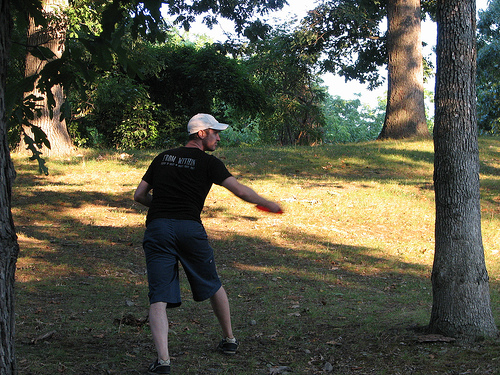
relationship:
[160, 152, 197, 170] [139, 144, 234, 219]
print on shirt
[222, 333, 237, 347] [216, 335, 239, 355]
socks in shoe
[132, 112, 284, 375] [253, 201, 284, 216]
man throwing frisbee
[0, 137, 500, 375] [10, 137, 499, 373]
leaves on ground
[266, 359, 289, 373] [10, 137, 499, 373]
leaves on ground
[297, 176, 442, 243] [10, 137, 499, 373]
sunny area on ground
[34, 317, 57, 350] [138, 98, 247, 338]
stick behind man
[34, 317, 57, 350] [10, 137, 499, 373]
stick on ground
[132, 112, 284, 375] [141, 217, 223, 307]
man wearing shorts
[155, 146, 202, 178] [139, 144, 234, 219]
writing on shirt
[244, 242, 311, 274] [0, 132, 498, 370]
shadow on grass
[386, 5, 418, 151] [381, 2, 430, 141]
shadow on tree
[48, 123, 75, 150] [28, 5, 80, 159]
sunlight on tree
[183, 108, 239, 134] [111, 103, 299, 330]
hat on man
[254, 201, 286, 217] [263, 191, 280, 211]
frisbee in hand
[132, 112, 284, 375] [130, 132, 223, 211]
man on shirt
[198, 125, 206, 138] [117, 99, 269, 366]
ear on man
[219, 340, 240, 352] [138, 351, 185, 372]
shoe on foot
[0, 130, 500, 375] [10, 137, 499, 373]
grass on ground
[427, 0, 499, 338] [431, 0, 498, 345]
bark on tree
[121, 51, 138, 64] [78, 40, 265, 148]
leaf on tree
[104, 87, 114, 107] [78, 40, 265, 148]
leaf on tree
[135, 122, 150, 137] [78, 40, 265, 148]
leaf on tree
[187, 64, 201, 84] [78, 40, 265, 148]
leaf on tree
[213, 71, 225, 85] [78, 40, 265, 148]
leaf on tree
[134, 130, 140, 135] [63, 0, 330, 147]
leaf on tree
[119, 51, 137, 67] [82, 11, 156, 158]
leaf on tree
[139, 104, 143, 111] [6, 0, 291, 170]
leaf on tree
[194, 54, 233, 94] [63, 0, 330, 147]
leaf on tree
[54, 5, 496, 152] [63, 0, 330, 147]
green leaf on tree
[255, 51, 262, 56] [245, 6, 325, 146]
leaf on tree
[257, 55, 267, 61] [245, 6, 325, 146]
leaf on tree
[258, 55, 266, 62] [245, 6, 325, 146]
leaf on tree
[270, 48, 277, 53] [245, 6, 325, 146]
leaf on tree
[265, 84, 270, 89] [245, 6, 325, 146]
leaf on tree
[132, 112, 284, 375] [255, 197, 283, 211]
man playing with frisbee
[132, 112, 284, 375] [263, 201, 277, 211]
man has hand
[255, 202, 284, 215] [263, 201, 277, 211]
frisbee in hand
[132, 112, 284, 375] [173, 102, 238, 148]
man wearing hat.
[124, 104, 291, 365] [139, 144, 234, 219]
man wearing shirt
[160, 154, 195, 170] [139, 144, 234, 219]
writing on shirt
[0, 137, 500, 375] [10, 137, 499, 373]
leaves scattered on ground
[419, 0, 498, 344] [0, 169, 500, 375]
tree casting shadow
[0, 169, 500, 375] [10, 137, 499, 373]
shadow on ground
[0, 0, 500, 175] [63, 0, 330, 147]
green leaf on tree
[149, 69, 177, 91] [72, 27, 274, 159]
leaf on tree